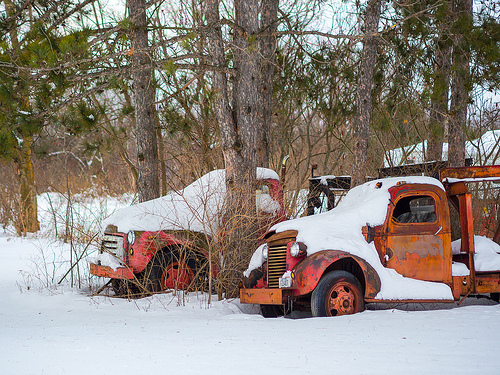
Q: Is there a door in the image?
A: Yes, there is a door.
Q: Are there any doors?
A: Yes, there is a door.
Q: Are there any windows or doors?
A: Yes, there is a door.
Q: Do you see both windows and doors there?
A: Yes, there are both a door and a window.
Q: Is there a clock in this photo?
A: No, there are no clocks.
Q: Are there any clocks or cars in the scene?
A: No, there are no clocks or cars.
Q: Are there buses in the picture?
A: No, there are no buses.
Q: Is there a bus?
A: No, there are no buses.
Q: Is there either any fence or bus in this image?
A: No, there are no buses or fences.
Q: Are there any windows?
A: Yes, there is a window.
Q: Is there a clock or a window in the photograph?
A: Yes, there is a window.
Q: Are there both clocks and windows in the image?
A: No, there is a window but no clocks.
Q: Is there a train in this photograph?
A: No, there are no trains.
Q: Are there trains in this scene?
A: No, there are no trains.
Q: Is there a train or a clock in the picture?
A: No, there are no trains or clocks.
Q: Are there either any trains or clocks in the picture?
A: No, there are no trains or clocks.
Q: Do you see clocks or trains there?
A: No, there are no trains or clocks.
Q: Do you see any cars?
A: No, there are no cars.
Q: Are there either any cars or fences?
A: No, there are no cars or fences.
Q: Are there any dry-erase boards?
A: No, there are no dry-erase boards.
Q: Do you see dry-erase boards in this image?
A: No, there are no dry-erase boards.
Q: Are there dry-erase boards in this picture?
A: No, there are no dry-erase boards.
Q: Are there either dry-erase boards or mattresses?
A: No, there are no dry-erase boards or mattresses.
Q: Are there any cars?
A: No, there are no cars.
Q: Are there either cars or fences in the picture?
A: No, there are no cars or fences.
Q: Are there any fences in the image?
A: No, there are no fences.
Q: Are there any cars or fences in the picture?
A: No, there are no fences or cars.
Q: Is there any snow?
A: Yes, there is snow.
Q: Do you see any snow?
A: Yes, there is snow.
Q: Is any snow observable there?
A: Yes, there is snow.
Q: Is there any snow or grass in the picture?
A: Yes, there is snow.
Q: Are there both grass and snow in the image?
A: No, there is snow but no grass.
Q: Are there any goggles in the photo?
A: No, there are no goggles.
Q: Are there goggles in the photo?
A: No, there are no goggles.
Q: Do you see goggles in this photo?
A: No, there are no goggles.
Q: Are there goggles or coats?
A: No, there are no goggles or coats.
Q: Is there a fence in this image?
A: No, there are no fences.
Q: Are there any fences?
A: No, there are no fences.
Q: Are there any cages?
A: No, there are no cages.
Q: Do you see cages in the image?
A: No, there are no cages.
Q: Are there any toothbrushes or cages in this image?
A: No, there are no cages or toothbrushes.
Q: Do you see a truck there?
A: Yes, there is a truck.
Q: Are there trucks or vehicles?
A: Yes, there is a truck.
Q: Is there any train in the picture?
A: No, there are no trains.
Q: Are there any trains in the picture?
A: No, there are no trains.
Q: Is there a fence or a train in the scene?
A: No, there are no trains or fences.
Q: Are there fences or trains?
A: No, there are no trains or fences.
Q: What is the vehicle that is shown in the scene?
A: The vehicle is a truck.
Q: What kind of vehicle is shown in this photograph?
A: The vehicle is a truck.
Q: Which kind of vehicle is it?
A: The vehicle is a truck.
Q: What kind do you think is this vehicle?
A: This is a truck.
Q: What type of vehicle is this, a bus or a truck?
A: This is a truck.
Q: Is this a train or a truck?
A: This is a truck.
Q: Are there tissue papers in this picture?
A: No, there are no tissue papers.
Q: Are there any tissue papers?
A: No, there are no tissue papers.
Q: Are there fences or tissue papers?
A: No, there are no tissue papers or fences.